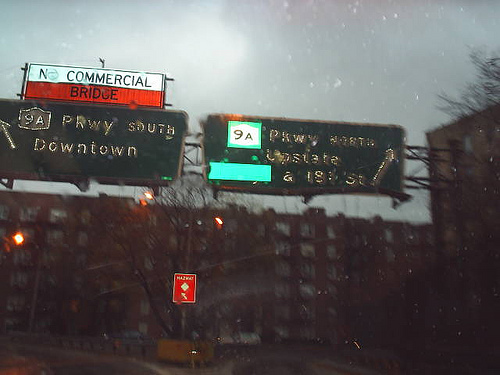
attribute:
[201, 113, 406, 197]
sign — giving directions, for drivers, large, rectangular, suspended, black, dirty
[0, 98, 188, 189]
sign — giving directions, for drivers, large, rectangular, green, suspended, black, dirty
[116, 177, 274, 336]
tree — leafless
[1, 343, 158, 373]
road — diverging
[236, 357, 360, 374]
road — a ramp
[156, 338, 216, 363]
bumper — safety bumper, yellow, a barrier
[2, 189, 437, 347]
housing unit — large, red, brick, tall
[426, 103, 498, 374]
housing unit — large, brick, tall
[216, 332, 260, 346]
car — parked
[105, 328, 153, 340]
car — parked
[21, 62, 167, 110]
sign — describing bridge, rectangular, red, white, dirty, orange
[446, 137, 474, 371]
post — metal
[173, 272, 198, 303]
sign — red, white, dirty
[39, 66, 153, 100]
writing — black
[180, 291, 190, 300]
arrow — white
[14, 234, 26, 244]
light — shining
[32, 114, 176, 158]
letters — white, reflective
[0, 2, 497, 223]
sky — cloudy, gray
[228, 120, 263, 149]
patch — bright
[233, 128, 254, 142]
text — black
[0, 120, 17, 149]
arrow — white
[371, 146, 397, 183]
arrow — white